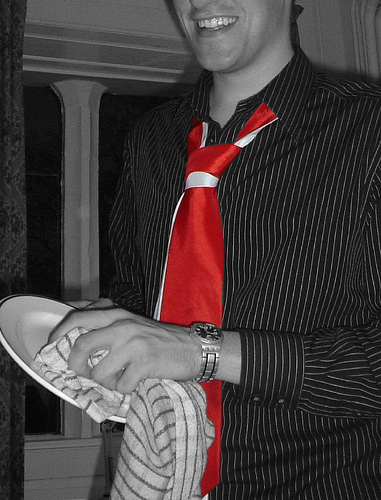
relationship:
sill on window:
[25, 433, 128, 477] [23, 26, 207, 301]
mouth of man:
[194, 14, 237, 35] [49, 1, 381, 500]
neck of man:
[208, 71, 284, 128] [49, 1, 381, 500]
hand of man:
[47, 301, 199, 393] [49, 1, 381, 500]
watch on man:
[188, 323, 225, 384] [49, 1, 381, 500]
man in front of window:
[49, 1, 381, 500] [23, 26, 207, 301]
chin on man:
[197, 47, 250, 70] [49, 1, 381, 500]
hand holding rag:
[47, 301, 199, 393] [32, 341, 216, 499]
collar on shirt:
[240, 46, 314, 143] [109, 48, 380, 499]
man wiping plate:
[49, 1, 381, 500] [0, 292, 76, 406]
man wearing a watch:
[49, 1, 381, 500] [188, 323, 225, 384]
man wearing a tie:
[49, 1, 381, 500] [153, 143, 241, 325]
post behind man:
[49, 79, 111, 299] [49, 1, 381, 500]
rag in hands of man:
[32, 341, 216, 499] [49, 1, 381, 500]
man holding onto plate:
[49, 1, 381, 500] [0, 292, 76, 406]